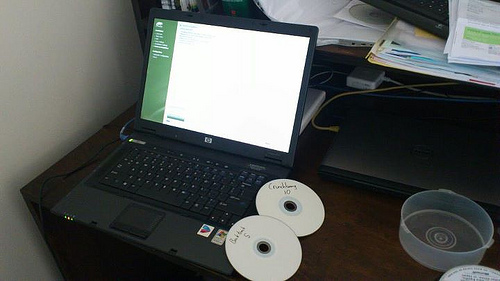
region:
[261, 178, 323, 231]
a white cd disk on the laptop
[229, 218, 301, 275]
another white disk on the computer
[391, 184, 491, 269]
the top of the cd case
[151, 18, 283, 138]
the screen of the laptop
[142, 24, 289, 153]
the laptop computers screen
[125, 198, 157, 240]
track pad on the laptop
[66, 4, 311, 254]
a black laptop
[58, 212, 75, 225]
green and yellow lights on the laptop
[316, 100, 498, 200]
a laptop is closed on the table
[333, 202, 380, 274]
a brown table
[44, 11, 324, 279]
laptop is open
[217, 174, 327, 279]
two discs are on a keyboard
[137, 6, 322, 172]
laptop screen is on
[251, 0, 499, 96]
papers are piled on a desk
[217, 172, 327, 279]
data discs are white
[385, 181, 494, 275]
plastic lid of a blank cd spindle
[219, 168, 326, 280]
cd's have holes in the center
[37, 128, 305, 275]
black laptop keyboard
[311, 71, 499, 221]
closed grey laptop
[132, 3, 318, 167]
screen is white with a green band on the left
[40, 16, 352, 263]
open laptop in photo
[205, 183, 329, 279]
two discs next to laptop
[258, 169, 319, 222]
disc with writing on it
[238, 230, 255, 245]
number five on disc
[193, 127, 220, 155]
logo on the laptop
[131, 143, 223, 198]
keys on the keyboard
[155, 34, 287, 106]
program open on laptop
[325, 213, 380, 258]
brown table next to laptop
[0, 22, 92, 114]
wall next to table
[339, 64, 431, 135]
cords near the laptop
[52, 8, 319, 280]
a black laptop on desk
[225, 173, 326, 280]
two DVDs propped against a laptop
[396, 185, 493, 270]
a round plastic cover on a desk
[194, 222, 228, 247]
stickers on a laptop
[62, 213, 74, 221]
LED lights on a laptop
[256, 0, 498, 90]
a bunch of papers on a shelf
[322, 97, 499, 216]
a closed laptop on a desk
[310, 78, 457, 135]
a yellow plug and wire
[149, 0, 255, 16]
books on a shelf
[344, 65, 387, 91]
a small white plastic box on a desk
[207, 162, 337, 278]
THESE ARE TWO CDS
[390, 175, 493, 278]
THIS IS A PLASTIC CD CASE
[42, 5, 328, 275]
THIS IS A LAPTOP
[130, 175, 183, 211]
THIS IS THE SPACE BAR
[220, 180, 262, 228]
THIS IS THE ENTER KEY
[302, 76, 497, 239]
THIS IS A ROUTER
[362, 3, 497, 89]
THESE PAPERS ARE ON THE SHELF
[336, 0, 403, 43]
THIS CD IS INSIDE A CASE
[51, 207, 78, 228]
THESE ARE LIGHTS ON THE COMP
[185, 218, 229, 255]
THESE ARE LOGO STICKERS